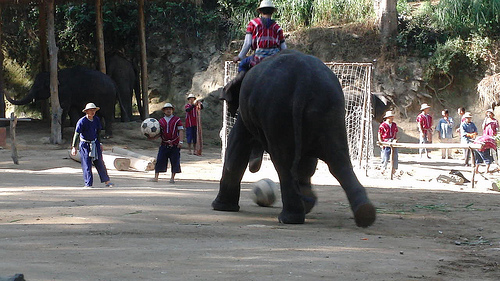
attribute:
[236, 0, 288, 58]
man — riding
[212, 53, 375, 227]
elephant — playing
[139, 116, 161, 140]
soccer ball — large, oversized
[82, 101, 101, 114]
brimmed hat — wide brimmed, large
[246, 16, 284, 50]
shirt — red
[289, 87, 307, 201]
elephants tail — long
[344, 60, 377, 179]
goal — net, white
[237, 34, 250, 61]
shirt — gray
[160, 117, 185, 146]
shirts — red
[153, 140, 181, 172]
shorts — cut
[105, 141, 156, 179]
logs — heavy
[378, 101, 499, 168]
people — standing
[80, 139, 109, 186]
pants — blue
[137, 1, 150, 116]
tree trunks — brown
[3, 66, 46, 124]
trunk — curved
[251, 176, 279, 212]
ball — large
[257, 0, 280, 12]
hat — sun hat, wide brimmed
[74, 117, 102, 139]
shirt — blue